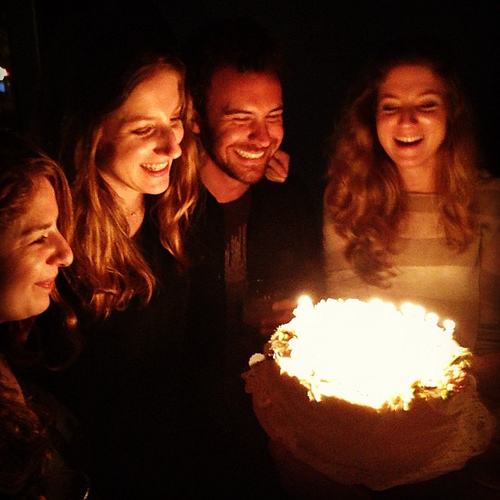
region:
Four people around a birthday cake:
[0, 49, 497, 496]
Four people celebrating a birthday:
[0, 39, 494, 499]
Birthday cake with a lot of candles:
[247, 290, 494, 488]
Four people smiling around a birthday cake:
[0, 50, 496, 498]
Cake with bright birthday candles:
[265, 290, 479, 475]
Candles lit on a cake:
[262, 293, 474, 478]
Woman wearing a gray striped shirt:
[315, 50, 499, 383]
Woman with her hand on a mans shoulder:
[45, 43, 291, 361]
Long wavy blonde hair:
[325, 54, 480, 287]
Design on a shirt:
[217, 220, 249, 291]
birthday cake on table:
[258, 291, 470, 480]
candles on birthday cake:
[298, 295, 450, 410]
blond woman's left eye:
[415, 97, 441, 112]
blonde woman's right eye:
[380, 103, 401, 114]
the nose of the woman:
[397, 108, 418, 130]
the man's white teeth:
[233, 147, 269, 158]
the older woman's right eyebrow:
[16, 226, 58, 238]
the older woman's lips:
[29, 279, 63, 289]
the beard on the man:
[231, 144, 273, 186]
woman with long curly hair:
[340, 167, 380, 244]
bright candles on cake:
[303, 297, 378, 373]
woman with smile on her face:
[132, 155, 178, 181]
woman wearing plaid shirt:
[413, 230, 428, 270]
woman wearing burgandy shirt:
[7, 388, 47, 466]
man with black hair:
[222, 46, 265, 71]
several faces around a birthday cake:
[14, 22, 481, 409]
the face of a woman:
[380, 83, 440, 154]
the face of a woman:
[126, 100, 186, 182]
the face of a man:
[223, 100, 280, 169]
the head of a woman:
[367, 55, 459, 177]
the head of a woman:
[80, 53, 194, 215]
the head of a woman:
[0, 150, 78, 325]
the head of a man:
[195, 33, 301, 193]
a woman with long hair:
[68, 35, 190, 317]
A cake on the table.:
[265, 296, 442, 461]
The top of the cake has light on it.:
[302, 293, 429, 387]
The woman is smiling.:
[368, 120, 445, 170]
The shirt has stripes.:
[316, 200, 497, 320]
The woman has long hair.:
[316, 106, 396, 254]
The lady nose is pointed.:
[49, 234, 79, 260]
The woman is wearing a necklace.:
[116, 198, 161, 222]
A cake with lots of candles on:
[238, 276, 470, 462]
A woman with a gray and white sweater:
[324, 155, 482, 323]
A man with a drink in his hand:
[181, 251, 313, 372]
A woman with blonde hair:
[17, 60, 200, 210]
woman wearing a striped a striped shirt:
[320, 57, 499, 404]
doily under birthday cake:
[240, 291, 497, 488]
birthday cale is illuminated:
[263, 287, 478, 472]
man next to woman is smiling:
[175, 57, 327, 397]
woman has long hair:
[46, 48, 225, 498]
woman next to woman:
[2, 145, 77, 498]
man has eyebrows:
[217, 105, 283, 116]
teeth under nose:
[233, 148, 266, 160]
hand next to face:
[263, 150, 291, 184]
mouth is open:
[394, 133, 423, 146]